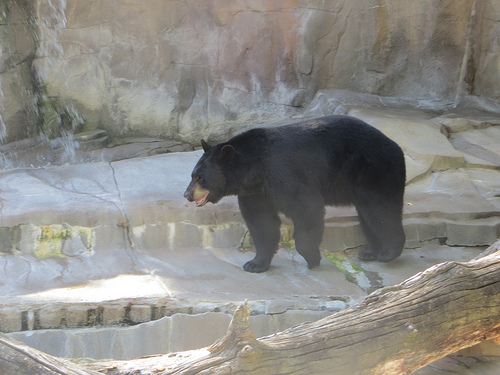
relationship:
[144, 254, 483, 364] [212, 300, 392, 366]
log of tree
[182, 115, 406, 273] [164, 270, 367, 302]
bear walking surface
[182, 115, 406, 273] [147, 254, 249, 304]
bear walking surface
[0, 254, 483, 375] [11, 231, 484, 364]
log from tree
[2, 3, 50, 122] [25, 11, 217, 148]
crack in rock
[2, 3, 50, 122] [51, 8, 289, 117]
crack in rock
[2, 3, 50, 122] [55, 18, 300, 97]
crack in rock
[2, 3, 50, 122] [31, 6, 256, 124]
crack in rock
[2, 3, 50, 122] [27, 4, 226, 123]
crack in rock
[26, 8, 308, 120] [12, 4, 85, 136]
crack in rock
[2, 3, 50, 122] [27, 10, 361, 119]
crack in rock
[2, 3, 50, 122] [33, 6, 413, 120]
crack in rock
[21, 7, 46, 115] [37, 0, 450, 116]
crack in rock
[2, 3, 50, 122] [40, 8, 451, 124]
crack in rock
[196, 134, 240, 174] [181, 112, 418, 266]
ear of bear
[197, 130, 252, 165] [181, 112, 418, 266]
ear of bear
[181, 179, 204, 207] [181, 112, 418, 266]
nose of bear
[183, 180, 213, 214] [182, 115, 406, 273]
mouth of bear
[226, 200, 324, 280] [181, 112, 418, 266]
legs of bear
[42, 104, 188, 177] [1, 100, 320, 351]
moss on rocks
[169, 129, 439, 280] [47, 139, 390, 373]
bear on rock